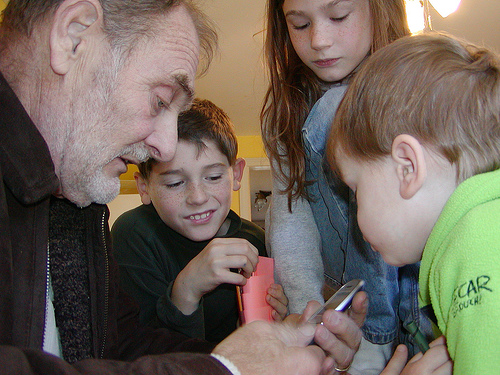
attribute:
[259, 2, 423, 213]
hair — long, brown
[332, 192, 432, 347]
jacket — blue , denim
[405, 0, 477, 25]
light — on, ceiling light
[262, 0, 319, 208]
brown hair — long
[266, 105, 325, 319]
sweatshirt — grey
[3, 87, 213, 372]
coat — fur-lined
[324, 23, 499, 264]
hair — light brown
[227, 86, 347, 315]
sweater — gray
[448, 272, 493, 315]
lettering — dark green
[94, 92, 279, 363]
little boy — smiling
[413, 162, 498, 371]
sweater — green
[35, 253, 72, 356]
shirt — white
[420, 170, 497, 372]
shirt — green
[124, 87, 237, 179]
hair — brown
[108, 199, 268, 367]
shirt — black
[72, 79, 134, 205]
beard — grey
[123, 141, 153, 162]
mustache — grey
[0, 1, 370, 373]
man — talking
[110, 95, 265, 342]
boy — smiling